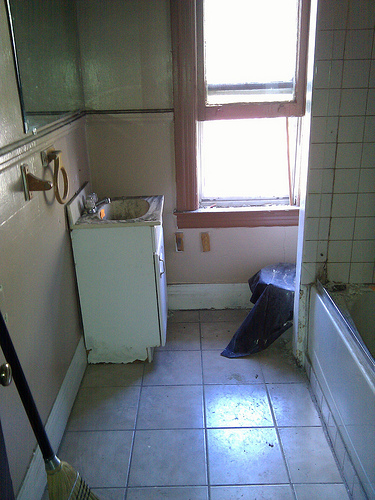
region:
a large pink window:
[165, 16, 299, 228]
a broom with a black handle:
[0, 306, 101, 498]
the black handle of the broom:
[0, 314, 64, 467]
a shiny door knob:
[1, 360, 11, 387]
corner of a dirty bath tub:
[300, 270, 365, 375]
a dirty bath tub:
[302, 278, 373, 496]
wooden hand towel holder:
[39, 142, 70, 205]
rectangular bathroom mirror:
[2, 1, 86, 134]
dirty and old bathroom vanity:
[66, 178, 168, 364]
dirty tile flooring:
[125, 377, 293, 495]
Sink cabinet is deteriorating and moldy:
[60, 298, 169, 393]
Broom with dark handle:
[2, 349, 127, 497]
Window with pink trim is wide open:
[163, 79, 294, 250]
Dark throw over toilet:
[223, 249, 316, 386]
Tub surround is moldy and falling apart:
[288, 246, 372, 404]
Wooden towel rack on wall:
[9, 143, 77, 220]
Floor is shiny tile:
[173, 378, 321, 494]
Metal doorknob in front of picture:
[0, 342, 39, 424]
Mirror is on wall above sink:
[9, 74, 147, 263]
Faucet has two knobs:
[66, 177, 159, 258]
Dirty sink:
[64, 185, 171, 243]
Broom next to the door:
[3, 309, 112, 497]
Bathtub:
[303, 278, 373, 499]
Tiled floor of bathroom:
[54, 293, 341, 499]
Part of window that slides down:
[196, 4, 305, 117]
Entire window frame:
[175, 4, 311, 236]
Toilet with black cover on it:
[239, 249, 315, 368]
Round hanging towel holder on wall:
[41, 149, 90, 218]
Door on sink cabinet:
[146, 251, 173, 284]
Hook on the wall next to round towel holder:
[16, 160, 62, 211]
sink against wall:
[76, 184, 186, 389]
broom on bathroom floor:
[0, 343, 113, 496]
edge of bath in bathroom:
[307, 271, 371, 493]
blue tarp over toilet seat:
[207, 243, 343, 376]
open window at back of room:
[153, 0, 311, 240]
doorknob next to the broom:
[0, 356, 24, 390]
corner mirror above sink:
[3, 0, 175, 138]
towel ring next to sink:
[34, 138, 86, 213]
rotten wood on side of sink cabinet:
[79, 334, 170, 370]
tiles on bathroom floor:
[16, 256, 364, 496]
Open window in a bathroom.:
[169, 3, 314, 228]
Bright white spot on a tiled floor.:
[204, 386, 283, 466]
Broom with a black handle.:
[1, 312, 99, 498]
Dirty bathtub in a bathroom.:
[303, 280, 373, 499]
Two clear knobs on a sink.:
[82, 191, 97, 210]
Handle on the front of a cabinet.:
[157, 255, 167, 280]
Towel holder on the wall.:
[53, 149, 70, 204]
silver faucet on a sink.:
[96, 197, 111, 208]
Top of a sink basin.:
[64, 181, 164, 228]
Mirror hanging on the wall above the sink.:
[4, 0, 85, 133]